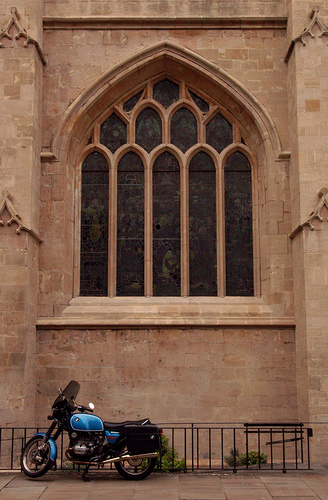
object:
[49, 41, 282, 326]
arched window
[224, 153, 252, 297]
window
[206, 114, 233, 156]
window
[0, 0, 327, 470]
building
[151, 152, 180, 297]
window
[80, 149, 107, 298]
window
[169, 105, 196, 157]
window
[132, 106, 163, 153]
window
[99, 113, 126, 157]
window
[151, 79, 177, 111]
window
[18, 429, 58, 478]
tire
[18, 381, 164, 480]
motorcycle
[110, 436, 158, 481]
tire